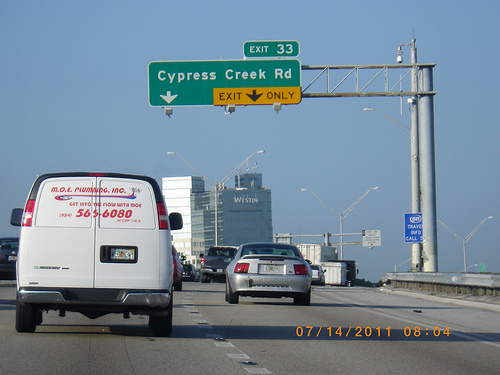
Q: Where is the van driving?
A: On the street.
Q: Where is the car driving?
A: On the street.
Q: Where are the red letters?
A: On the back end of the white van.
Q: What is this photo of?
A: A highway.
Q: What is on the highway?
A: Traffic.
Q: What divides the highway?
A: A divider.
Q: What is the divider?
A: A broken white line.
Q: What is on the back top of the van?
A: A number.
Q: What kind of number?
A: A phone number.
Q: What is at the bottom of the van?
A: A license plate.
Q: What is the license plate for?
A: To identify the car.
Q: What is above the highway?
A: A highway sign.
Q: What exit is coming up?
A: Exit 33 to Cypress Creek Rd.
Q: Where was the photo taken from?
A: A car.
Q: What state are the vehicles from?
A: Florida.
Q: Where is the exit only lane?
A: The right lane.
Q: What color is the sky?
A: Blue.